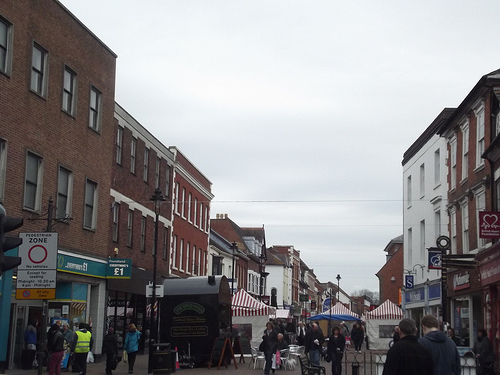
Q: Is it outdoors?
A: Yes, it is outdoors.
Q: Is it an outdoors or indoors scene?
A: It is outdoors.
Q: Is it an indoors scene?
A: No, it is outdoors.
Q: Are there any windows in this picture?
A: Yes, there is a window.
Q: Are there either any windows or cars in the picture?
A: Yes, there is a window.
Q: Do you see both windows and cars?
A: No, there is a window but no cars.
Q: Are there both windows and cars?
A: No, there is a window but no cars.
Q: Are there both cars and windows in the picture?
A: No, there is a window but no cars.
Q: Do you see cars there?
A: No, there are no cars.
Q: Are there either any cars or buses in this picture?
A: No, there are no cars or buses.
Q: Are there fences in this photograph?
A: No, there are no fences.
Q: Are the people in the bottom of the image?
A: Yes, the people are in the bottom of the image.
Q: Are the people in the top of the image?
A: No, the people are in the bottom of the image.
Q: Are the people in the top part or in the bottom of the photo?
A: The people are in the bottom of the image.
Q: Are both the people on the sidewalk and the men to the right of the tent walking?
A: Yes, both the people and the men are walking.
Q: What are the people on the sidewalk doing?
A: The people are walking.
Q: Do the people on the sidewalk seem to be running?
A: No, the people are walking.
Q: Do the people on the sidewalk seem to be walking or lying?
A: The people are walking.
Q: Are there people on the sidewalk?
A: Yes, there are people on the sidewalk.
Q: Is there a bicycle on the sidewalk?
A: No, there are people on the sidewalk.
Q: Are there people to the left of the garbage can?
A: Yes, there are people to the left of the garbage can.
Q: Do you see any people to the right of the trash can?
A: No, the people are to the left of the trash can.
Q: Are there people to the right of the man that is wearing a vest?
A: Yes, there are people to the right of the man.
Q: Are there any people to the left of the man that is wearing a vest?
A: No, the people are to the right of the man.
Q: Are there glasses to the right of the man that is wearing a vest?
A: No, there are people to the right of the man.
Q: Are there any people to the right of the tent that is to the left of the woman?
A: No, the people are to the left of the tent.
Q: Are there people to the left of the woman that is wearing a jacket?
A: Yes, there are people to the left of the woman.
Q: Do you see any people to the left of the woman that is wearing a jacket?
A: Yes, there are people to the left of the woman.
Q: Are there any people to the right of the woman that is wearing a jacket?
A: No, the people are to the left of the woman.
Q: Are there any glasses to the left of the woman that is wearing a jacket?
A: No, there are people to the left of the woman.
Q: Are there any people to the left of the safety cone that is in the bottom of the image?
A: Yes, there are people to the left of the traffic cone.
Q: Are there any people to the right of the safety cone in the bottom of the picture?
A: No, the people are to the left of the cone.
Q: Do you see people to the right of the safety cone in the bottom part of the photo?
A: No, the people are to the left of the cone.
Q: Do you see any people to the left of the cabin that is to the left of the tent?
A: Yes, there are people to the left of the cabin.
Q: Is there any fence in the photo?
A: No, there are no fences.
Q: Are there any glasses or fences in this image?
A: No, there are no fences or glasses.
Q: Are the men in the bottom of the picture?
A: Yes, the men are in the bottom of the image.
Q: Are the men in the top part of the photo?
A: No, the men are in the bottom of the image.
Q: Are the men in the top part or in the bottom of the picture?
A: The men are in the bottom of the image.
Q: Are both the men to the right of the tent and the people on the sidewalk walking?
A: Yes, both the men and the people are walking.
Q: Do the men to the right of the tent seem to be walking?
A: Yes, the men are walking.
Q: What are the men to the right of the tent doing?
A: The men are walking.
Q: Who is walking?
A: The men are walking.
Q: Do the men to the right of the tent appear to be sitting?
A: No, the men are walking.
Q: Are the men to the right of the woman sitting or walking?
A: The men are walking.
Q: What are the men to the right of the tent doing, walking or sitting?
A: The men are walking.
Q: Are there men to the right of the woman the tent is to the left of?
A: Yes, there are men to the right of the woman.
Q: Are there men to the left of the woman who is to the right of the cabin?
A: No, the men are to the right of the woman.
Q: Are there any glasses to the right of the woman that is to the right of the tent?
A: No, there are men to the right of the woman.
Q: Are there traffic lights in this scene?
A: Yes, there is a traffic light.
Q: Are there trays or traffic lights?
A: Yes, there is a traffic light.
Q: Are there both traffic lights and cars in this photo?
A: No, there is a traffic light but no cars.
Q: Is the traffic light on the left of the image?
A: Yes, the traffic light is on the left of the image.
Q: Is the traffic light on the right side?
A: No, the traffic light is on the left of the image.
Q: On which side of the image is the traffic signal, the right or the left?
A: The traffic signal is on the left of the image.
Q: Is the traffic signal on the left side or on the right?
A: The traffic signal is on the left of the image.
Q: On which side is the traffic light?
A: The traffic light is on the left of the image.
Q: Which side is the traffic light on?
A: The traffic light is on the left of the image.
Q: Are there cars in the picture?
A: No, there are no cars.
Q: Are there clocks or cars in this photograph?
A: No, there are no cars or clocks.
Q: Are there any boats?
A: No, there are no boats.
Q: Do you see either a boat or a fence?
A: No, there are no boats or fences.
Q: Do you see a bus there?
A: No, there are no buses.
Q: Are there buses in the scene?
A: No, there are no buses.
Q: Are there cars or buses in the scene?
A: No, there are no buses or cars.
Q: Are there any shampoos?
A: No, there are no shampoos.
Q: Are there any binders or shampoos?
A: No, there are no shampoos or binders.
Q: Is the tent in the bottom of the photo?
A: Yes, the tent is in the bottom of the image.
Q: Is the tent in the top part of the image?
A: No, the tent is in the bottom of the image.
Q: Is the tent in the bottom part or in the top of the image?
A: The tent is in the bottom of the image.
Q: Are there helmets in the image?
A: No, there are no helmets.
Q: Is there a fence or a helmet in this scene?
A: No, there are no helmets or fences.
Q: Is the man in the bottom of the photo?
A: Yes, the man is in the bottom of the image.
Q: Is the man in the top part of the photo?
A: No, the man is in the bottom of the image.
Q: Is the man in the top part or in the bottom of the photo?
A: The man is in the bottom of the image.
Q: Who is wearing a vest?
A: The man is wearing a vest.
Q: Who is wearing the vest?
A: The man is wearing a vest.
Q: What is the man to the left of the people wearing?
A: The man is wearing a vest.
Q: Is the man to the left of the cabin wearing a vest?
A: Yes, the man is wearing a vest.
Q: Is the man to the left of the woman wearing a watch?
A: No, the man is wearing a vest.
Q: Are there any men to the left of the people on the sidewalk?
A: Yes, there is a man to the left of the people.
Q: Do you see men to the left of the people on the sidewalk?
A: Yes, there is a man to the left of the people.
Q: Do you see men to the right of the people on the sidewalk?
A: No, the man is to the left of the people.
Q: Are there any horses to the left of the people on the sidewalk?
A: No, there is a man to the left of the people.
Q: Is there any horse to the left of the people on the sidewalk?
A: No, there is a man to the left of the people.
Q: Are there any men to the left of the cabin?
A: Yes, there is a man to the left of the cabin.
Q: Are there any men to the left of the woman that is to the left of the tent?
A: Yes, there is a man to the left of the woman.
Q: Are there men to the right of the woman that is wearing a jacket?
A: No, the man is to the left of the woman.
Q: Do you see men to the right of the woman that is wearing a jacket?
A: No, the man is to the left of the woman.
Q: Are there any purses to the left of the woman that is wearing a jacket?
A: No, there is a man to the left of the woman.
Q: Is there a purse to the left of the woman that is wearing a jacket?
A: No, there is a man to the left of the woman.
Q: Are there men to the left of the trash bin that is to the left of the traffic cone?
A: Yes, there is a man to the left of the trash bin.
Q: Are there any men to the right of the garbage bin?
A: No, the man is to the left of the garbage bin.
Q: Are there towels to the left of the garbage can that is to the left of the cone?
A: No, there is a man to the left of the trashcan.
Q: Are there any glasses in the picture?
A: No, there are no glasses.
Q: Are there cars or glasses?
A: No, there are no glasses or cars.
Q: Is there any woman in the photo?
A: Yes, there is a woman.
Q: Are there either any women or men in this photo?
A: Yes, there is a woman.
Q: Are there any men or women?
A: Yes, there is a woman.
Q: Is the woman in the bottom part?
A: Yes, the woman is in the bottom of the image.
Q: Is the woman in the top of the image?
A: No, the woman is in the bottom of the image.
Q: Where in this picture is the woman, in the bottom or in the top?
A: The woman is in the bottom of the image.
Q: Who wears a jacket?
A: The woman wears a jacket.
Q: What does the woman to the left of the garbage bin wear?
A: The woman wears a jacket.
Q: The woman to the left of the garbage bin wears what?
A: The woman wears a jacket.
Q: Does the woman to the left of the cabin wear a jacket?
A: Yes, the woman wears a jacket.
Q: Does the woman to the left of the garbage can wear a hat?
A: No, the woman wears a jacket.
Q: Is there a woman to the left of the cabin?
A: Yes, there is a woman to the left of the cabin.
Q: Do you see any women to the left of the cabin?
A: Yes, there is a woman to the left of the cabin.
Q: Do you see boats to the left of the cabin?
A: No, there is a woman to the left of the cabin.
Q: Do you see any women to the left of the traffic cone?
A: Yes, there is a woman to the left of the traffic cone.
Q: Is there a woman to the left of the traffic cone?
A: Yes, there is a woman to the left of the traffic cone.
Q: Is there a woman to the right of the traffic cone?
A: No, the woman is to the left of the traffic cone.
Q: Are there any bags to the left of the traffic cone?
A: No, there is a woman to the left of the traffic cone.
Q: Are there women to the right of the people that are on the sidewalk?
A: Yes, there is a woman to the right of the people.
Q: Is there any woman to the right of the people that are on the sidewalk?
A: Yes, there is a woman to the right of the people.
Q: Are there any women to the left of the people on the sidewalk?
A: No, the woman is to the right of the people.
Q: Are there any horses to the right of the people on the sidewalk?
A: No, there is a woman to the right of the people.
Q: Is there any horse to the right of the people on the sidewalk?
A: No, there is a woman to the right of the people.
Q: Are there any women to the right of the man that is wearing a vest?
A: Yes, there is a woman to the right of the man.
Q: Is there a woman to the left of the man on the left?
A: No, the woman is to the right of the man.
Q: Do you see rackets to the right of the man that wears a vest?
A: No, there is a woman to the right of the man.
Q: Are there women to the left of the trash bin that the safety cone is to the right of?
A: Yes, there is a woman to the left of the trash bin.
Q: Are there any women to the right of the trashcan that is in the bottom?
A: No, the woman is to the left of the trashcan.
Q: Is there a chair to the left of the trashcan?
A: No, there is a woman to the left of the trashcan.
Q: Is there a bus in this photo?
A: No, there are no buses.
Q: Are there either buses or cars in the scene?
A: No, there are no buses or cars.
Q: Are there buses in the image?
A: No, there are no buses.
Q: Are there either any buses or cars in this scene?
A: No, there are no buses or cars.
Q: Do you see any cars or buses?
A: No, there are no buses or cars.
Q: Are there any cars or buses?
A: No, there are no buses or cars.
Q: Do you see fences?
A: No, there are no fences.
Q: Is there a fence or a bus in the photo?
A: No, there are no fences or buses.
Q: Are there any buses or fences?
A: No, there are no fences or buses.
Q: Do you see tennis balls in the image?
A: No, there are no tennis balls.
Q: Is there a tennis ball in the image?
A: No, there are no tennis balls.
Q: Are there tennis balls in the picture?
A: No, there are no tennis balls.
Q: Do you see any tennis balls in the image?
A: No, there are no tennis balls.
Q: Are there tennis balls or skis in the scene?
A: No, there are no tennis balls or skis.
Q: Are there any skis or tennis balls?
A: No, there are no tennis balls or skis.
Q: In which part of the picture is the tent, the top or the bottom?
A: The tent is in the bottom of the image.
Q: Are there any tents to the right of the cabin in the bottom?
A: Yes, there is a tent to the right of the cabin.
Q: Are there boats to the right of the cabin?
A: No, there is a tent to the right of the cabin.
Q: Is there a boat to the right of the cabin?
A: No, there is a tent to the right of the cabin.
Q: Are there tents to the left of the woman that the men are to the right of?
A: Yes, there is a tent to the left of the woman.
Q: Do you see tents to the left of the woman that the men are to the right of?
A: Yes, there is a tent to the left of the woman.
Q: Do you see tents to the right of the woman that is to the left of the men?
A: No, the tent is to the left of the woman.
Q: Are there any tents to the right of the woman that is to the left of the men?
A: No, the tent is to the left of the woman.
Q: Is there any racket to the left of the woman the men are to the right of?
A: No, there is a tent to the left of the woman.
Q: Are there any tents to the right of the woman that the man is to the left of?
A: Yes, there is a tent to the right of the woman.